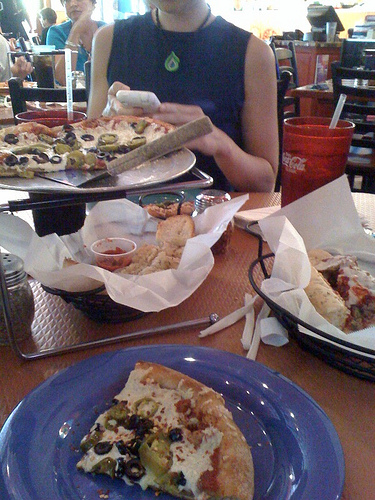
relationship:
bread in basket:
[62, 213, 194, 275] [39, 281, 153, 323]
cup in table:
[279, 115, 357, 210] [0, 185, 374, 497]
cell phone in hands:
[113, 86, 164, 115] [104, 77, 221, 152]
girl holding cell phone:
[82, 3, 286, 198] [113, 86, 164, 115]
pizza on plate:
[78, 357, 255, 500] [13, 344, 353, 498]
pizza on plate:
[88, 368, 278, 498] [13, 344, 353, 498]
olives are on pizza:
[124, 462, 146, 480] [76, 363, 252, 498]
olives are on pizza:
[134, 418, 150, 431] [76, 363, 252, 498]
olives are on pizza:
[94, 440, 110, 450] [76, 363, 252, 498]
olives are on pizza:
[168, 431, 180, 440] [76, 363, 252, 498]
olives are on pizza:
[117, 439, 127, 452] [76, 363, 252, 498]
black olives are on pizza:
[117, 436, 144, 480] [78, 357, 255, 500]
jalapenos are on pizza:
[141, 428, 173, 472] [78, 357, 255, 500]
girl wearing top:
[82, 0, 283, 198] [82, 17, 269, 159]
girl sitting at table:
[82, 0, 283, 198] [2, 184, 370, 451]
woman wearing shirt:
[43, 2, 108, 84] [45, 19, 106, 72]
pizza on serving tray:
[12, 117, 168, 181] [2, 143, 206, 192]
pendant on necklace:
[158, 52, 186, 72] [151, 7, 210, 72]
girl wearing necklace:
[82, 0, 283, 198] [151, 7, 210, 72]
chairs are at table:
[273, 28, 373, 158] [289, 71, 373, 109]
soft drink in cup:
[31, 53, 53, 86] [28, 42, 59, 87]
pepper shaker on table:
[0, 247, 40, 351] [0, 185, 374, 497]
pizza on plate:
[78, 357, 255, 500] [210, 336, 304, 442]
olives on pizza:
[32, 150, 63, 165] [81, 329, 272, 497]